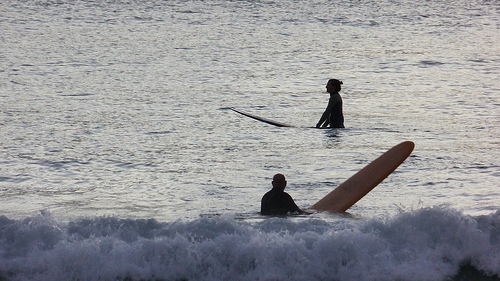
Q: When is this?
A: Daytime.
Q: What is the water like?
A: Calm.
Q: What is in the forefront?
A: Waves.